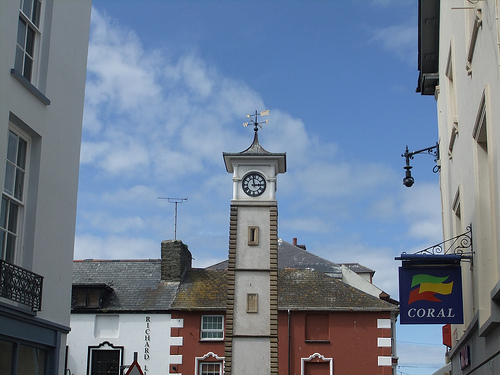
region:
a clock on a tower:
[216, 104, 298, 374]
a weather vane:
[236, 96, 296, 178]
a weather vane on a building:
[225, 63, 287, 363]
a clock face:
[242, 171, 267, 197]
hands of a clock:
[251, 173, 266, 190]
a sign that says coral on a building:
[394, 217, 494, 345]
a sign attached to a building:
[381, 11, 498, 357]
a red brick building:
[171, 207, 398, 374]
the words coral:
[403, 303, 463, 324]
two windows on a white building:
[1, 7, 71, 325]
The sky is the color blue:
[118, 9, 375, 90]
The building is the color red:
[292, 306, 374, 361]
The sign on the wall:
[391, 219, 477, 329]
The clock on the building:
[233, 162, 273, 197]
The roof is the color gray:
[78, 241, 231, 303]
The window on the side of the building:
[0, 9, 60, 279]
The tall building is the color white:
[216, 105, 293, 372]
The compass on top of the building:
[238, 102, 277, 134]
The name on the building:
[133, 309, 156, 374]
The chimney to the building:
[156, 230, 194, 287]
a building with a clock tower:
[94, 101, 409, 373]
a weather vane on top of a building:
[243, 104, 273, 146]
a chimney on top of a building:
[158, 236, 192, 282]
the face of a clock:
[240, 166, 268, 197]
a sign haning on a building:
[395, 234, 482, 328]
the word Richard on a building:
[141, 310, 151, 362]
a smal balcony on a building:
[1, 248, 54, 319]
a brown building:
[174, 309, 399, 374]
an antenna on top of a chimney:
[151, 192, 191, 245]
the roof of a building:
[110, 257, 172, 307]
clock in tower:
[234, 165, 286, 218]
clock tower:
[212, 100, 279, 372]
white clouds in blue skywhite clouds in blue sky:
[342, 37, 359, 59]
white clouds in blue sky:
[243, 40, 302, 78]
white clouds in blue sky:
[87, 4, 151, 47]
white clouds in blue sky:
[132, 22, 181, 92]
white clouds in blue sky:
[283, 114, 363, 171]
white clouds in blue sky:
[95, 180, 150, 241]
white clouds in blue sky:
[155, 155, 203, 212]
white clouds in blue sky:
[319, 195, 363, 222]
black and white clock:
[234, 162, 268, 212]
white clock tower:
[224, 111, 285, 373]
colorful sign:
[387, 251, 462, 324]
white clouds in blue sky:
[174, 38, 199, 61]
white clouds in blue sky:
[142, 84, 169, 127]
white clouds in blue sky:
[311, 59, 356, 95]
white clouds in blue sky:
[337, 84, 382, 135]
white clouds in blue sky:
[112, 125, 152, 150]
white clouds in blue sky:
[125, 159, 176, 204]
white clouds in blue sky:
[191, 62, 221, 101]